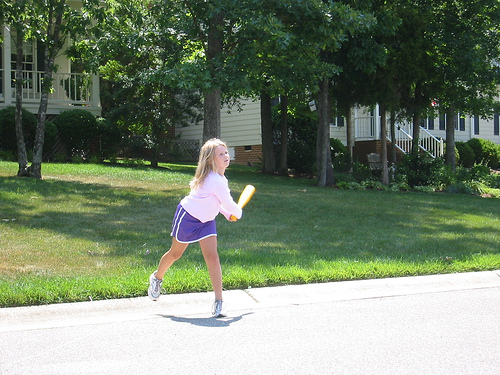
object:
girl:
[148, 138, 242, 317]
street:
[0, 270, 500, 374]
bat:
[231, 184, 256, 222]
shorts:
[170, 203, 217, 243]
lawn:
[0, 159, 500, 308]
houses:
[1, 0, 102, 120]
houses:
[174, 53, 500, 171]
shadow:
[155, 312, 253, 327]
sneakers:
[211, 299, 224, 318]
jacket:
[180, 170, 242, 223]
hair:
[189, 138, 227, 190]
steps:
[385, 114, 444, 158]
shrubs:
[52, 107, 97, 163]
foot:
[148, 270, 164, 301]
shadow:
[0, 165, 499, 268]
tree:
[0, 0, 85, 179]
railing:
[0, 69, 93, 108]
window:
[244, 146, 252, 151]